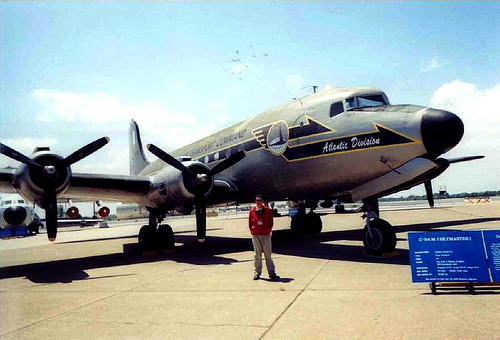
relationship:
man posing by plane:
[247, 194, 282, 282] [92, 118, 360, 205]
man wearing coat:
[247, 195, 279, 281] [246, 205, 274, 238]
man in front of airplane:
[247, 194, 282, 282] [0, 86, 496, 258]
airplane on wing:
[0, 82, 486, 256] [3, 161, 231, 220]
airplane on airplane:
[0, 82, 486, 256] [0, 86, 496, 258]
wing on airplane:
[3, 161, 231, 220] [0, 86, 496, 258]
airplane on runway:
[3, 81, 486, 276] [2, 194, 489, 335]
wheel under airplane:
[271, 167, 403, 254] [0, 82, 486, 256]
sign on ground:
[406, 226, 499, 284] [0, 201, 499, 338]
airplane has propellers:
[0, 82, 486, 256] [3, 136, 242, 246]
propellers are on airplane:
[21, 125, 219, 245] [0, 82, 486, 256]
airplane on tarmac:
[0, 82, 486, 256] [10, 207, 498, 336]